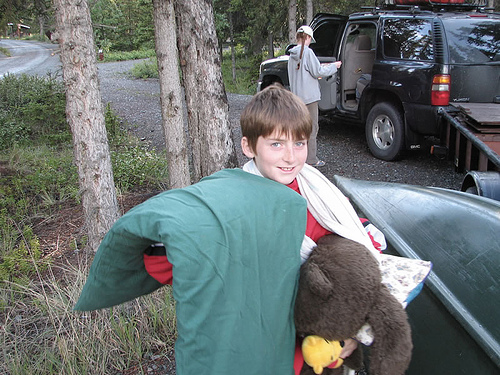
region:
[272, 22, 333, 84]
a woman wearing a white hat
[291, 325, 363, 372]
a pooh bear stuffed animal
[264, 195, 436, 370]
a brown teddy bear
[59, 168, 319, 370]
a green body pillow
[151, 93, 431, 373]
a boy holding a pooh stuffed animal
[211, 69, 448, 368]
a boy holding a brown teddy bear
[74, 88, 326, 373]
a boy holding a green pillow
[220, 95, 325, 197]
a boy with brown hair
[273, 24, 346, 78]
a woman with her hair braided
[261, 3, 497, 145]
a black suv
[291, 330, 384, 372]
Boy holding a Winnie the Poo stuffed animal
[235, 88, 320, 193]
Boy with light brown hair and blue eyes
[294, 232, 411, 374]
Big brown stuffed animal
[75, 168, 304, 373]
Boy holding a big green pollow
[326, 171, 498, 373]
A green kayak upside down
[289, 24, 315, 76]
Girl with long pigtails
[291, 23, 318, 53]
Girl wearing a white hat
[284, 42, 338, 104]
Girl wearing a grey sweater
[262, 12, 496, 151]
Black dirty van with the door open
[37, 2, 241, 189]
Bark of trees cluttered together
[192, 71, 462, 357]
Little boy on a camping trip.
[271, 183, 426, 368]
Man with a bear.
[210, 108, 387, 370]
Boy holding a bear.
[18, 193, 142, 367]
Grass by the tree.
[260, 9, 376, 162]
Woman by the truck.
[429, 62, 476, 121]
Windows on the SUV.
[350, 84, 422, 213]
Wheel on the SUV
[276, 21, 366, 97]
Woman with a braid.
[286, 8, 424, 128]
Door on the SUV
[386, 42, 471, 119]
Red and orange light.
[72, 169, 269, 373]
boy holding a green pillow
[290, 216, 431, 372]
boy holding a teddy bear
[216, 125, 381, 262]
boy with a white sheet around his neck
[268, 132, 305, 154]
boy with blue eyes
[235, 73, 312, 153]
boy with brown hair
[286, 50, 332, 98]
girl wearing a grey sweatshirt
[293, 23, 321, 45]
girl wearing a white hat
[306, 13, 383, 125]
door open on a SUV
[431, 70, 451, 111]
Lights on a SUV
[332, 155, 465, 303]
boat on a trailer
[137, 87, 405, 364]
boy going to camp